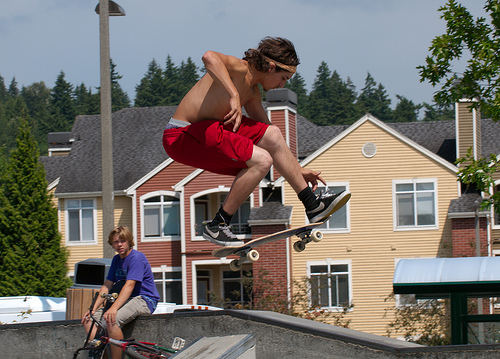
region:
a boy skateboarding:
[138, 25, 355, 275]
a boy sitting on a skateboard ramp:
[63, 219, 200, 356]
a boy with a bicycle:
[63, 220, 218, 356]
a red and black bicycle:
[63, 293, 180, 358]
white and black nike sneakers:
[171, 173, 389, 300]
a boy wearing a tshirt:
[85, 200, 154, 340]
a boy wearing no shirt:
[178, 36, 308, 171]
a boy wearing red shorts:
[159, 43, 328, 202]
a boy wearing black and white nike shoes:
[173, 42, 351, 234]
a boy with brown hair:
[231, 42, 328, 121]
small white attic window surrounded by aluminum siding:
[350, 133, 388, 168]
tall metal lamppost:
[91, 0, 131, 181]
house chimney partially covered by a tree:
[450, 68, 484, 182]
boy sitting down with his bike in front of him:
[67, 219, 183, 357]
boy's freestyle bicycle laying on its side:
[71, 287, 183, 357]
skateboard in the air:
[213, 218, 333, 278]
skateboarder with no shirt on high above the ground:
[145, 23, 362, 358]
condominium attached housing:
[16, 86, 499, 336]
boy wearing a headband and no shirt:
[161, 35, 350, 247]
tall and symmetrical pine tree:
[1, 116, 75, 304]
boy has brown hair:
[238, 34, 318, 96]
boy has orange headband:
[207, 31, 317, 95]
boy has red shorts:
[168, 70, 273, 170]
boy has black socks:
[272, 165, 327, 222]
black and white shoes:
[300, 188, 361, 219]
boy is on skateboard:
[195, 185, 353, 266]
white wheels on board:
[208, 225, 342, 265]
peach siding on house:
[321, 148, 466, 336]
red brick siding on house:
[141, 151, 281, 306]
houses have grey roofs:
[84, 107, 186, 192]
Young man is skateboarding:
[140, 20, 375, 270]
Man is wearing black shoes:
[186, 186, 359, 268]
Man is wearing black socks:
[196, 177, 331, 234]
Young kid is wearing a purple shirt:
[101, 247, 161, 322]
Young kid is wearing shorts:
[78, 290, 172, 338]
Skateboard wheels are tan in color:
[219, 223, 329, 275]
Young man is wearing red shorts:
[156, 106, 274, 185]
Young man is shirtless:
[171, 45, 285, 158]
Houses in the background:
[28, 95, 498, 344]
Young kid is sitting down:
[71, 214, 163, 357]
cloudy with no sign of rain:
[310, 15, 422, 55]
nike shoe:
[201, 220, 243, 247]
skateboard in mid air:
[208, 217, 326, 268]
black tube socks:
[293, 183, 317, 204]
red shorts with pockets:
[153, 120, 271, 160]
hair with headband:
[242, 35, 301, 75]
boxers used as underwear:
[165, 116, 188, 128]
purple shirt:
[101, 253, 162, 300]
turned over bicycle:
[68, 290, 180, 357]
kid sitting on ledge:
[78, 223, 161, 357]